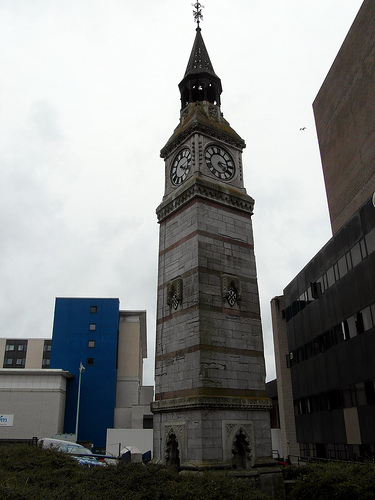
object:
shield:
[227, 288, 237, 306]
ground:
[1, 443, 374, 498]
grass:
[0, 439, 375, 499]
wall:
[0, 371, 60, 441]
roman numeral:
[217, 147, 221, 155]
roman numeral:
[223, 151, 227, 157]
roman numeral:
[226, 158, 232, 163]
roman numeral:
[227, 165, 233, 169]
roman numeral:
[211, 168, 217, 175]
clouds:
[1, 0, 199, 337]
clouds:
[258, 172, 316, 235]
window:
[222, 274, 242, 310]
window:
[337, 254, 348, 279]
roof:
[159, 100, 247, 152]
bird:
[299, 126, 306, 131]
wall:
[47, 293, 122, 457]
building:
[51, 290, 151, 456]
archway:
[221, 419, 255, 470]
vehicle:
[33, 435, 111, 470]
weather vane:
[189, 0, 204, 26]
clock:
[204, 143, 235, 180]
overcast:
[0, 0, 375, 385]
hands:
[217, 162, 225, 171]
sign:
[0, 413, 14, 428]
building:
[0, 369, 69, 459]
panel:
[335, 141, 371, 189]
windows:
[346, 316, 358, 340]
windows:
[360, 307, 374, 331]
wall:
[105, 429, 154, 462]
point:
[190, 0, 204, 33]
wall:
[153, 197, 208, 481]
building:
[144, 0, 273, 485]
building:
[267, 0, 375, 464]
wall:
[196, 124, 275, 473]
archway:
[159, 428, 181, 472]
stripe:
[155, 385, 269, 402]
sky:
[2, 4, 369, 388]